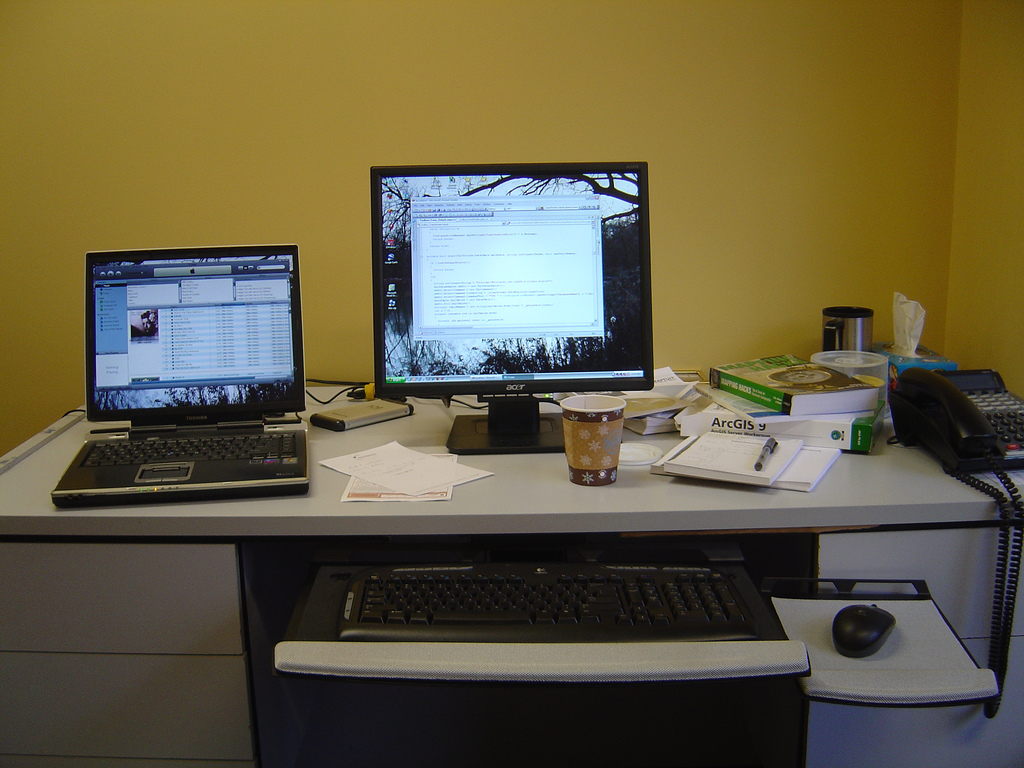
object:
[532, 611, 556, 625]
key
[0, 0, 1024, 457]
walls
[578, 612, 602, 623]
key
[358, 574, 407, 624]
keys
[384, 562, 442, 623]
keys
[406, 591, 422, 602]
key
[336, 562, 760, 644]
keyboard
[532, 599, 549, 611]
key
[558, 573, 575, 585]
key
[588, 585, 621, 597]
key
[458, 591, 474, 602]
key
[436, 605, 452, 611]
key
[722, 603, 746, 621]
key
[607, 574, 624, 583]
key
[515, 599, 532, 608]
key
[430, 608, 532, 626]
key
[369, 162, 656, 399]
screen